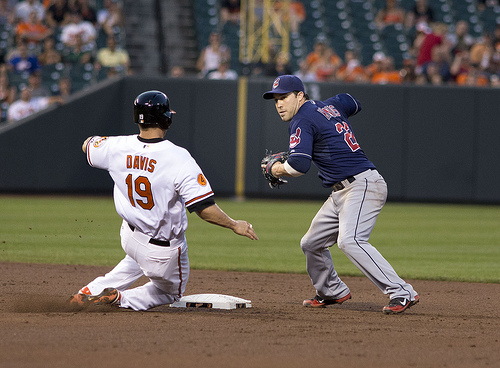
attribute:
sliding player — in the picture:
[85, 83, 254, 280]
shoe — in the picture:
[301, 287, 355, 309]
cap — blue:
[266, 74, 308, 97]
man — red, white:
[256, 67, 427, 319]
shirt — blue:
[279, 89, 380, 189]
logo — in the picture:
[287, 127, 302, 148]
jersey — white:
[82, 136, 229, 251]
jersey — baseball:
[275, 98, 410, 193]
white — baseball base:
[180, 289, 255, 316]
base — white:
[179, 292, 254, 315]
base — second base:
[180, 283, 258, 315]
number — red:
[123, 171, 134, 208]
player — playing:
[63, 82, 269, 315]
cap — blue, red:
[264, 73, 329, 110]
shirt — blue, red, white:
[285, 92, 375, 185]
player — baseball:
[221, 46, 438, 316]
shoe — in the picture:
[353, 286, 436, 317]